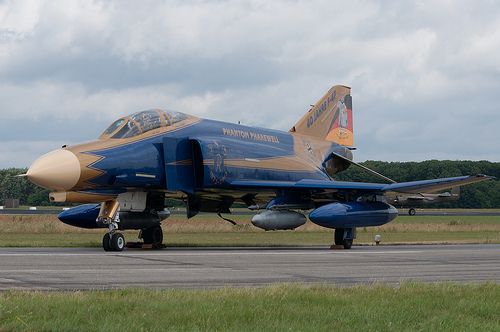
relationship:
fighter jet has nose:
[14, 81, 496, 253] [13, 147, 81, 195]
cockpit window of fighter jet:
[97, 110, 191, 132] [14, 81, 496, 253]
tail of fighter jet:
[294, 79, 363, 147] [14, 81, 496, 253]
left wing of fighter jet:
[238, 170, 492, 197] [14, 81, 496, 253]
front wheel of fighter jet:
[109, 231, 127, 253] [14, 81, 496, 253]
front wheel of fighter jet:
[99, 233, 110, 252] [14, 81, 496, 253]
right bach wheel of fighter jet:
[139, 226, 166, 247] [14, 81, 496, 253]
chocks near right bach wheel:
[127, 239, 151, 250] [139, 226, 166, 247]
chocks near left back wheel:
[327, 242, 344, 254] [335, 228, 355, 250]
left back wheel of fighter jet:
[335, 228, 355, 250] [14, 81, 496, 253]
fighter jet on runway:
[14, 81, 496, 253] [5, 242, 500, 285]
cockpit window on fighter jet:
[97, 110, 191, 132] [14, 81, 496, 253]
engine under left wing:
[311, 198, 403, 231] [238, 170, 492, 197]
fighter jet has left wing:
[14, 81, 496, 253] [238, 170, 492, 197]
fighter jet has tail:
[14, 81, 496, 253] [294, 79, 363, 147]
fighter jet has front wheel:
[14, 81, 496, 253] [103, 233, 110, 252]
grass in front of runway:
[11, 286, 497, 326] [5, 242, 500, 285]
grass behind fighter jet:
[6, 212, 500, 247] [14, 81, 496, 253]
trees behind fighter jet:
[1, 169, 48, 206] [14, 81, 496, 253]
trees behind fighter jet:
[358, 162, 500, 205] [14, 81, 496, 253]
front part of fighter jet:
[19, 103, 200, 207] [14, 81, 496, 253]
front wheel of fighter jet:
[103, 233, 110, 252] [14, 81, 496, 253]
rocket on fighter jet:
[243, 207, 312, 234] [14, 81, 496, 253]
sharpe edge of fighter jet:
[12, 169, 36, 184] [14, 81, 496, 253]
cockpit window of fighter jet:
[99, 109, 191, 141] [14, 81, 496, 253]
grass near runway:
[11, 286, 497, 326] [5, 242, 500, 285]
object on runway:
[373, 230, 385, 251] [5, 242, 500, 285]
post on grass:
[25, 204, 40, 211] [2, 198, 76, 212]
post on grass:
[58, 203, 74, 212] [2, 198, 76, 212]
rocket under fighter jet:
[243, 207, 312, 234] [14, 81, 496, 253]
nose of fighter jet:
[13, 147, 81, 195] [14, 81, 496, 253]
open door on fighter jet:
[160, 128, 216, 200] [14, 81, 496, 253]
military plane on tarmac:
[386, 186, 468, 219] [400, 207, 499, 224]